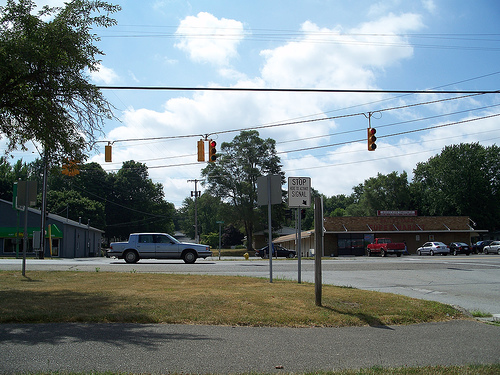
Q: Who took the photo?
A: Police.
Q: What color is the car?
A: Grey.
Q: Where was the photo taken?
A: Traffic stop.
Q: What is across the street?
A: Restaurant.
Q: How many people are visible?
A: Zero.